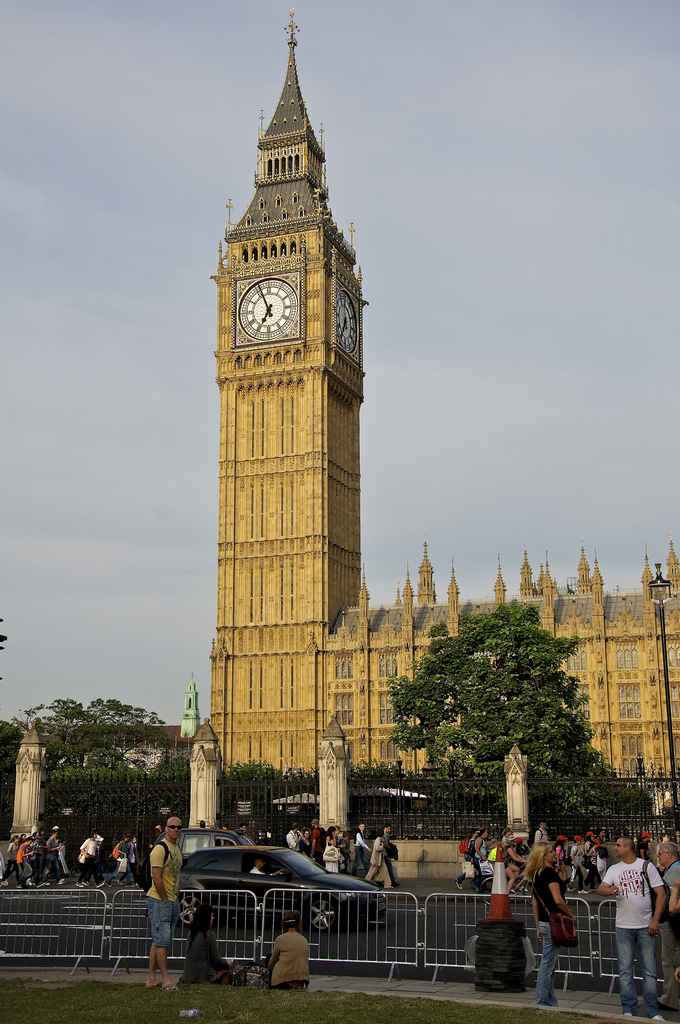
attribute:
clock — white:
[232, 268, 310, 350]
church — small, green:
[173, 665, 206, 740]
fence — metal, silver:
[5, 875, 677, 994]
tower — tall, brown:
[203, 8, 372, 783]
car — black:
[171, 840, 401, 944]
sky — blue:
[7, 7, 678, 544]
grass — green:
[1, 983, 654, 1022]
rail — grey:
[255, 881, 423, 981]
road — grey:
[13, 879, 125, 953]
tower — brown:
[202, 40, 354, 251]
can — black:
[454, 925, 536, 1009]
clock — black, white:
[233, 273, 304, 337]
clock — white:
[244, 268, 317, 354]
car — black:
[168, 828, 383, 941]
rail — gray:
[269, 875, 503, 984]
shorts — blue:
[138, 884, 185, 948]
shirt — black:
[523, 867, 569, 910]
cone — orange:
[492, 856, 514, 920]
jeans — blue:
[604, 913, 662, 995]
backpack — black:
[136, 841, 173, 883]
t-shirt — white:
[534, 871, 561, 917]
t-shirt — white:
[605, 856, 666, 932]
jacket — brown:
[272, 930, 309, 976]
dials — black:
[247, 283, 293, 329]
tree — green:
[386, 596, 650, 813]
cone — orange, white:
[477, 837, 522, 926]